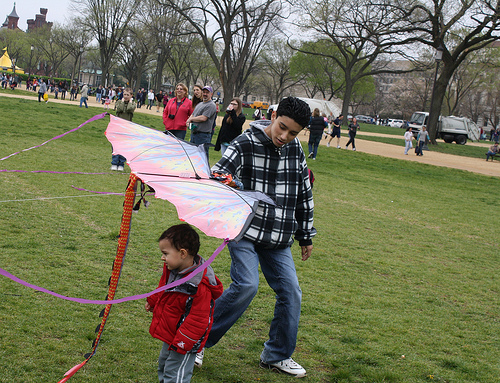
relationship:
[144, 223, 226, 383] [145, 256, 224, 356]
boy in a coat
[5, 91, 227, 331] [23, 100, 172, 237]
tails on kite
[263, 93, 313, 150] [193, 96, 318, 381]
hair on boy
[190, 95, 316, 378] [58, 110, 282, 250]
boys playing with kite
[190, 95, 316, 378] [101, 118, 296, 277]
boys playing with kite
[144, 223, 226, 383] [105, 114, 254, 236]
boy playing with kite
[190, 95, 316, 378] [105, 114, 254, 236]
boys playing with kite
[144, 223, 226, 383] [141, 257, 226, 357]
boy wearing coat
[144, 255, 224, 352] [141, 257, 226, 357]
boy wearing coat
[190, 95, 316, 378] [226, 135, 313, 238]
boys wearing hoodie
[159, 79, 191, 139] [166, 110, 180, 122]
person wearing camera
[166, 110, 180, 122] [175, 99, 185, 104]
camera around neck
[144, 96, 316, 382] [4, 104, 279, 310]
boys playing with kite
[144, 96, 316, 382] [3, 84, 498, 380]
boys in grass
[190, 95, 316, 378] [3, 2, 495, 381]
boys in park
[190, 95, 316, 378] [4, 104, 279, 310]
boys playing with kite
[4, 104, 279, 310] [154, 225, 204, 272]
kite on top of head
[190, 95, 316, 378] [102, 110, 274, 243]
boys holding kite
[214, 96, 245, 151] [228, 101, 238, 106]
lady wearing glasses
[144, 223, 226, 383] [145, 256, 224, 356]
boy wearing coat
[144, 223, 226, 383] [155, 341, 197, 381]
boy wearing grey trouser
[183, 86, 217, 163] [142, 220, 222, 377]
people in grass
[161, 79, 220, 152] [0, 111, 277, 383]
people standing and watching kite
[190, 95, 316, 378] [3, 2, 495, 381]
boys are at park